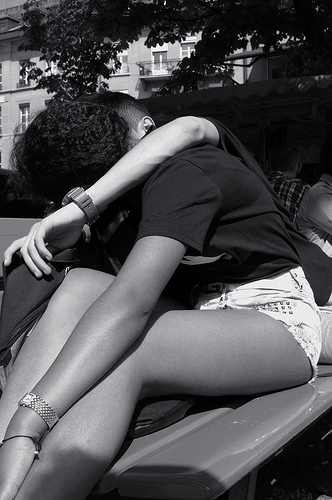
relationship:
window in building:
[154, 55, 160, 67] [1, 0, 327, 172]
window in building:
[21, 114, 27, 122] [1, 0, 327, 172]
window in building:
[111, 55, 125, 73] [1, 0, 327, 172]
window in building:
[21, 104, 29, 128] [1, 0, 327, 172]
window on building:
[21, 114, 27, 122] [1, 2, 330, 196]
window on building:
[149, 45, 169, 76] [1, 2, 330, 196]